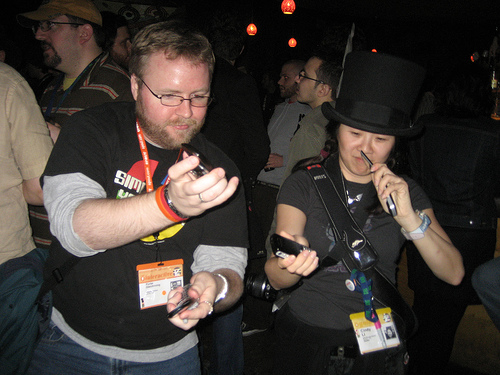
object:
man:
[25, 18, 254, 375]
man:
[23, 0, 124, 103]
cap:
[21, 1, 108, 34]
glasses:
[30, 18, 81, 35]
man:
[279, 54, 343, 199]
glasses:
[295, 70, 326, 90]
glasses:
[132, 70, 212, 114]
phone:
[164, 279, 199, 322]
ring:
[192, 191, 208, 209]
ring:
[198, 299, 216, 316]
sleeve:
[37, 111, 109, 191]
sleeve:
[198, 160, 252, 250]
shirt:
[37, 96, 250, 367]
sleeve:
[37, 120, 114, 265]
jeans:
[22, 309, 201, 374]